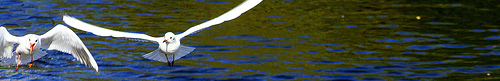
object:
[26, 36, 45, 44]
head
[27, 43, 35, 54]
beak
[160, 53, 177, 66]
feathers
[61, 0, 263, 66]
bird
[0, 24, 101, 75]
bird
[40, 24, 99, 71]
wing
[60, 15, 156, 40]
wing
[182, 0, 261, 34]
wings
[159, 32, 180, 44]
head